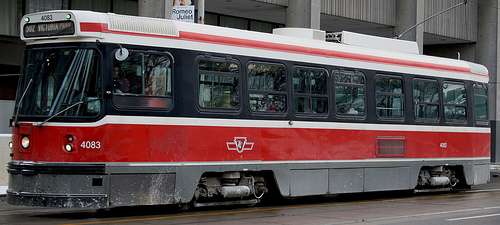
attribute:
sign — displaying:
[15, 19, 82, 39]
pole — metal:
[398, 2, 468, 29]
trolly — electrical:
[10, 12, 493, 207]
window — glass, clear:
[450, 86, 484, 120]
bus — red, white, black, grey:
[8, 8, 491, 210]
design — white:
[225, 135, 255, 152]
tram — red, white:
[1, 14, 302, 224]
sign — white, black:
[158, 0, 228, 23]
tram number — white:
[72, 139, 109, 149]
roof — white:
[119, 14, 490, 79]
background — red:
[14, 128, 494, 163]